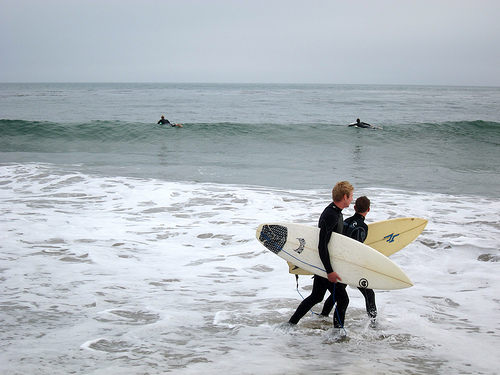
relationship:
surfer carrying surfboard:
[287, 184, 383, 338] [215, 197, 422, 313]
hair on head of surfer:
[328, 182, 360, 214] [287, 184, 383, 338]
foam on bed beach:
[1, 151, 499, 363] [8, 12, 498, 373]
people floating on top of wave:
[348, 118, 381, 130] [22, 77, 496, 178]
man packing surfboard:
[289, 181, 354, 328] [251, 220, 414, 291]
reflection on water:
[351, 128, 365, 168] [218, 109, 333, 206]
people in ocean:
[151, 112, 375, 137] [3, 81, 498, 366]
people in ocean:
[341, 116, 375, 139] [3, 81, 498, 366]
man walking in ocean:
[289, 181, 354, 328] [68, 207, 220, 275]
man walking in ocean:
[319, 196, 377, 337] [68, 207, 220, 275]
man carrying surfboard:
[289, 181, 354, 328] [251, 220, 414, 291]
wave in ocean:
[5, 119, 497, 169] [4, 81, 489, 111]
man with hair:
[289, 181, 354, 328] [314, 180, 371, 211]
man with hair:
[336, 197, 374, 330] [353, 194, 373, 216]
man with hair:
[325, 189, 385, 230] [351, 189, 385, 209]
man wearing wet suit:
[289, 181, 354, 328] [284, 194, 418, 342]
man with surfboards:
[319, 196, 377, 337] [259, 206, 486, 276]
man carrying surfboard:
[289, 181, 354, 328] [256, 222, 414, 290]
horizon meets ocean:
[1, 73, 482, 92] [3, 81, 498, 366]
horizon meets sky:
[1, 73, 482, 92] [0, 0, 494, 83]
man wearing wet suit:
[289, 181, 354, 328] [284, 199, 346, 338]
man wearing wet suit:
[319, 196, 377, 337] [318, 207, 380, 325]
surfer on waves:
[289, 181, 353, 329] [228, 97, 290, 147]